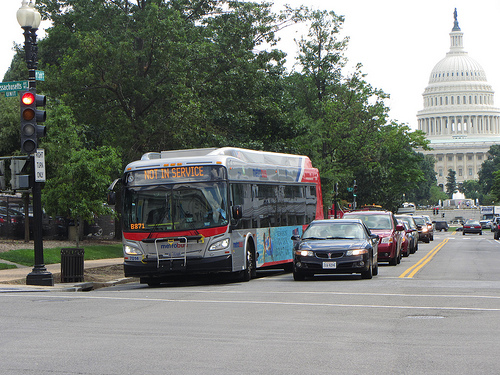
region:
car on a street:
[285, 216, 385, 285]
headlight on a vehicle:
[344, 247, 371, 258]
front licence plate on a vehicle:
[318, 258, 338, 274]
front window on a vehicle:
[296, 220, 371, 244]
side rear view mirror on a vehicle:
[227, 199, 245, 237]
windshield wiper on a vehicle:
[143, 189, 170, 242]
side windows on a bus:
[218, 177, 323, 234]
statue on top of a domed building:
[448, 2, 463, 34]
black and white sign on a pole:
[32, 147, 48, 184]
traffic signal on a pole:
[18, 84, 40, 160]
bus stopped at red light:
[111, 147, 325, 285]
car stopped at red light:
[290, 219, 382, 279]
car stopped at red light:
[339, 210, 404, 265]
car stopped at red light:
[393, 220, 411, 255]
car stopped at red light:
[391, 213, 421, 249]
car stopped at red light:
[411, 215, 428, 241]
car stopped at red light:
[422, 214, 433, 240]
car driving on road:
[462, 220, 484, 237]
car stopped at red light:
[487, 216, 497, 231]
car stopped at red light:
[492, 222, 497, 241]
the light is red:
[6, 87, 76, 167]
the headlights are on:
[274, 228, 389, 284]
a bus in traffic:
[95, 120, 277, 295]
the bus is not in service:
[111, 134, 236, 196]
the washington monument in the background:
[387, 0, 492, 202]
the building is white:
[392, 12, 491, 178]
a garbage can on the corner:
[37, 233, 95, 306]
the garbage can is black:
[46, 230, 100, 289]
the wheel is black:
[229, 232, 270, 282]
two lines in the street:
[392, 222, 461, 297]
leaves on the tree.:
[164, 50, 175, 63]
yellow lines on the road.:
[415, 255, 430, 269]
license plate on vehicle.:
[318, 260, 338, 272]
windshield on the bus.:
[187, 190, 204, 207]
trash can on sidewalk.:
[65, 250, 82, 273]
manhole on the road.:
[403, 311, 445, 331]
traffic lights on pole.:
[23, 93, 32, 135]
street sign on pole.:
[0, 81, 27, 93]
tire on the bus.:
[244, 245, 252, 282]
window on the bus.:
[287, 189, 302, 213]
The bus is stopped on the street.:
[108, 147, 287, 288]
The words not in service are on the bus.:
[143, 164, 205, 179]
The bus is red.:
[203, 224, 228, 236]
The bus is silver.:
[231, 249, 245, 271]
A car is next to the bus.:
[291, 218, 376, 280]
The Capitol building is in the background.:
[417, 6, 499, 129]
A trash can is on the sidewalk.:
[61, 248, 86, 282]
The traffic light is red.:
[19, 90, 39, 105]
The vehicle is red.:
[380, 229, 400, 256]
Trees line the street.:
[57, 18, 244, 135]